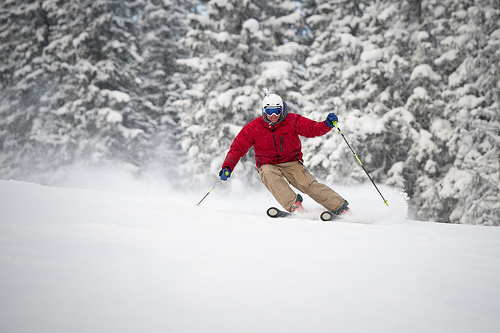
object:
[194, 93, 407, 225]
people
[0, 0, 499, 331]
outdoors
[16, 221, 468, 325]
ground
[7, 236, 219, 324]
snow